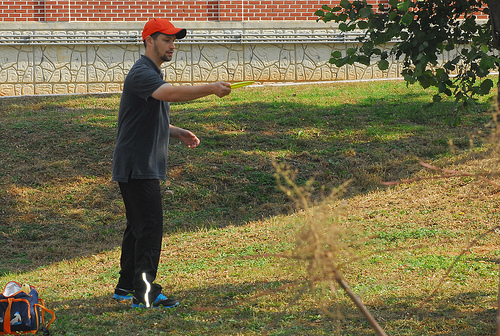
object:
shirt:
[111, 54, 170, 181]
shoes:
[112, 288, 133, 302]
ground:
[0, 73, 499, 335]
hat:
[141, 17, 188, 43]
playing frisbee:
[109, 16, 296, 261]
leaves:
[359, 8, 371, 19]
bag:
[2, 280, 38, 334]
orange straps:
[32, 303, 57, 334]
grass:
[0, 72, 499, 335]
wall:
[0, 0, 499, 98]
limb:
[185, 157, 474, 335]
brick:
[58, 17, 70, 21]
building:
[0, 0, 498, 97]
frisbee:
[228, 78, 254, 89]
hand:
[212, 81, 232, 98]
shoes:
[131, 293, 180, 312]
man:
[111, 16, 257, 311]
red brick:
[3, 18, 15, 23]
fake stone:
[0, 46, 35, 84]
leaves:
[376, 59, 390, 71]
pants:
[113, 170, 164, 309]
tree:
[313, 0, 500, 130]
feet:
[130, 293, 180, 311]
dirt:
[213, 263, 278, 288]